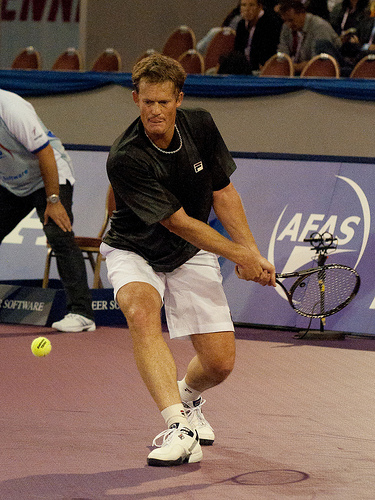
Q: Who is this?
A: Sportsman.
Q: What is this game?
A: Tennis.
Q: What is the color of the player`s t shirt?
A: Black.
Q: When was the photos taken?
A: Sports day.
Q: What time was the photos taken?
A: Day time.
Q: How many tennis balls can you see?
A: One.